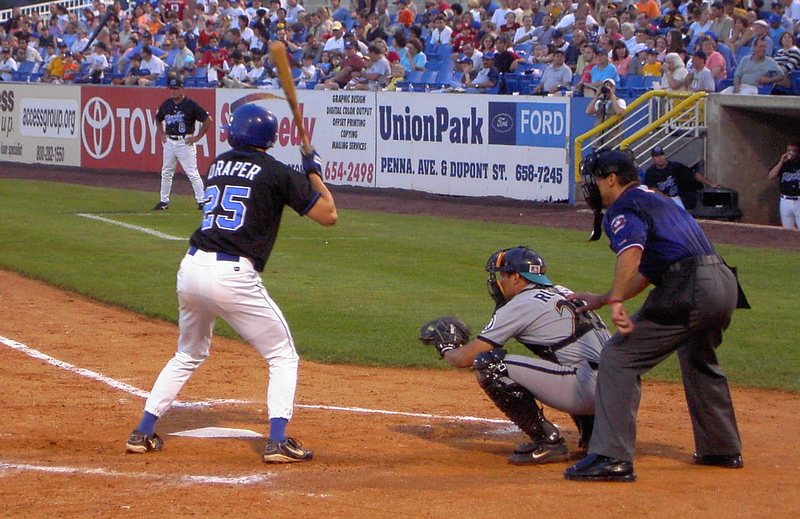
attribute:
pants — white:
[145, 247, 306, 418]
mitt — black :
[418, 313, 475, 355]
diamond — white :
[170, 418, 262, 444]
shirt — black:
[188, 146, 321, 266]